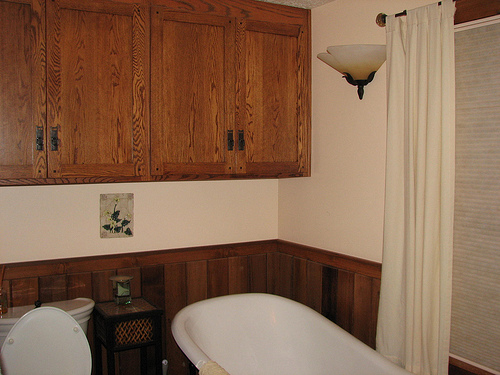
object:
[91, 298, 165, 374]
table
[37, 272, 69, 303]
paneling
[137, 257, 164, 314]
paneling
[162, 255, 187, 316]
paneling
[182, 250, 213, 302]
paneling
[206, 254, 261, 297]
paneling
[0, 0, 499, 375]
bathroom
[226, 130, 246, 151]
black handles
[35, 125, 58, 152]
black handles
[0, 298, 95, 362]
toilet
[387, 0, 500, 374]
window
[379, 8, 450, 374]
curtain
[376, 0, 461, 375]
blinds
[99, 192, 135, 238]
artwork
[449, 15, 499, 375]
shade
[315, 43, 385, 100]
light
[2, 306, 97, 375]
seat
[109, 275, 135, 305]
candle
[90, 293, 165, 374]
stand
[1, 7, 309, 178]
cavinets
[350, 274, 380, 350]
paneling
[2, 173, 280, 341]
wall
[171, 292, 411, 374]
bathtub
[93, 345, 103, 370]
leg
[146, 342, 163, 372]
leg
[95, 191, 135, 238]
tile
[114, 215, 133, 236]
leaves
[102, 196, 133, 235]
flowers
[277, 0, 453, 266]
wall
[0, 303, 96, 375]
lid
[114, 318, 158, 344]
pattern